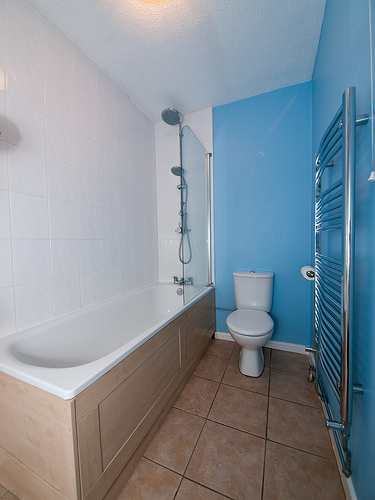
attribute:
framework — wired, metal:
[302, 86, 359, 440]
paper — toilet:
[300, 265, 314, 282]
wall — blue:
[206, 103, 313, 257]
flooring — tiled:
[104, 336, 349, 498]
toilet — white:
[222, 306, 279, 385]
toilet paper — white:
[298, 259, 317, 282]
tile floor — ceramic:
[148, 356, 347, 496]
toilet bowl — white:
[219, 268, 283, 345]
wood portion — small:
[72, 285, 216, 497]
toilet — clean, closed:
[228, 255, 284, 368]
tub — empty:
[29, 236, 266, 431]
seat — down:
[224, 307, 274, 337]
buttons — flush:
[247, 266, 260, 278]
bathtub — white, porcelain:
[2, 263, 234, 491]